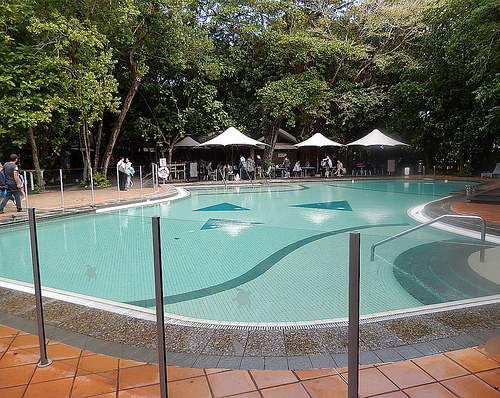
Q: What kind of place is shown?
A: It is a swimming pool.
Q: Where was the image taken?
A: It was taken at the swimming pool.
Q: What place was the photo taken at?
A: It was taken at the swimming pool.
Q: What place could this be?
A: It is a swimming pool.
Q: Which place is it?
A: It is a swimming pool.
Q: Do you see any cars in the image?
A: No, there are no cars.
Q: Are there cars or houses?
A: No, there are no cars or houses.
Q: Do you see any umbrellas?
A: Yes, there is an umbrella.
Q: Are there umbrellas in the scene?
A: Yes, there is an umbrella.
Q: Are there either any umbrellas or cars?
A: Yes, there is an umbrella.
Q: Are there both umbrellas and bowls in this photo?
A: No, there is an umbrella but no bowls.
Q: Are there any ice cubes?
A: No, there are no ice cubes.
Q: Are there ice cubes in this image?
A: No, there are no ice cubes.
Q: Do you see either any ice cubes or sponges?
A: No, there are no ice cubes or sponges.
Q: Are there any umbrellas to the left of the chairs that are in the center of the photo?
A: Yes, there is an umbrella to the left of the chairs.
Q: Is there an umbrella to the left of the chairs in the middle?
A: Yes, there is an umbrella to the left of the chairs.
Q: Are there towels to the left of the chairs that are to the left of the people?
A: No, there is an umbrella to the left of the chairs.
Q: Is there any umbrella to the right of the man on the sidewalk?
A: Yes, there is an umbrella to the right of the man.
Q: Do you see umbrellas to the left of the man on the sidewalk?
A: No, the umbrella is to the right of the man.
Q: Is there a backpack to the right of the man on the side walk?
A: No, there is an umbrella to the right of the man.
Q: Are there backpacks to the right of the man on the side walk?
A: No, there is an umbrella to the right of the man.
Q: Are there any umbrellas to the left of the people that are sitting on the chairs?
A: Yes, there is an umbrella to the left of the people.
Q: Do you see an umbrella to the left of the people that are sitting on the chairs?
A: Yes, there is an umbrella to the left of the people.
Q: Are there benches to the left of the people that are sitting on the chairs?
A: No, there is an umbrella to the left of the people.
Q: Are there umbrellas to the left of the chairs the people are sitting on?
A: Yes, there is an umbrella to the left of the chairs.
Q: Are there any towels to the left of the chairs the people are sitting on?
A: No, there is an umbrella to the left of the chairs.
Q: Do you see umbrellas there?
A: Yes, there is an umbrella.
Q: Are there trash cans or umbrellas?
A: Yes, there is an umbrella.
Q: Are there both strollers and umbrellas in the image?
A: No, there is an umbrella but no strollers.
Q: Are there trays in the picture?
A: No, there are no trays.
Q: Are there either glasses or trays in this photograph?
A: No, there are no trays or glasses.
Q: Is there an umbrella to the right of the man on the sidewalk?
A: Yes, there is an umbrella to the right of the man.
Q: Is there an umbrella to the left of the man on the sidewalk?
A: No, the umbrella is to the right of the man.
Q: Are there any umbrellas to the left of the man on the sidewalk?
A: No, the umbrella is to the right of the man.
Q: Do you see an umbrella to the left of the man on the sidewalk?
A: No, the umbrella is to the right of the man.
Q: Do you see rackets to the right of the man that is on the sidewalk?
A: No, there is an umbrella to the right of the man.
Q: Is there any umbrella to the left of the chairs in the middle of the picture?
A: Yes, there is an umbrella to the left of the chairs.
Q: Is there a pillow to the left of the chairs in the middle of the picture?
A: No, there is an umbrella to the left of the chairs.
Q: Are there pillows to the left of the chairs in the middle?
A: No, there is an umbrella to the left of the chairs.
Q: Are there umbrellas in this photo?
A: Yes, there is an umbrella.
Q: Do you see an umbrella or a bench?
A: Yes, there is an umbrella.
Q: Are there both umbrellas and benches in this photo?
A: No, there is an umbrella but no benches.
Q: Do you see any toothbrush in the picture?
A: No, there are no toothbrushes.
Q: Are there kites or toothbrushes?
A: No, there are no toothbrushes or kites.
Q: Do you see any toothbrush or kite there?
A: No, there are no toothbrushes or kites.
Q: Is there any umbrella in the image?
A: Yes, there is an umbrella.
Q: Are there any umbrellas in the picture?
A: Yes, there is an umbrella.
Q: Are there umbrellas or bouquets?
A: Yes, there is an umbrella.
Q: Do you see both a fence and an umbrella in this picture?
A: Yes, there are both an umbrella and a fence.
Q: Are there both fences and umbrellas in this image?
A: Yes, there are both an umbrella and a fence.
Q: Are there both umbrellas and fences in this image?
A: Yes, there are both an umbrella and a fence.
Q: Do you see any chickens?
A: No, there are no chickens.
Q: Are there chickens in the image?
A: No, there are no chickens.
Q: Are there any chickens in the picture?
A: No, there are no chickens.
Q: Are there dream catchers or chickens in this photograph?
A: No, there are no chickens or dream catchers.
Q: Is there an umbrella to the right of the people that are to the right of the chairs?
A: Yes, there is an umbrella to the right of the people.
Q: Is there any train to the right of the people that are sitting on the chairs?
A: No, there is an umbrella to the right of the people.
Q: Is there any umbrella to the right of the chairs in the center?
A: Yes, there is an umbrella to the right of the chairs.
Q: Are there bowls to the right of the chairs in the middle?
A: No, there is an umbrella to the right of the chairs.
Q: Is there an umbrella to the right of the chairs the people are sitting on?
A: Yes, there is an umbrella to the right of the chairs.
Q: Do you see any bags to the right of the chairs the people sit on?
A: No, there is an umbrella to the right of the chairs.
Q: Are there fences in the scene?
A: Yes, there is a fence.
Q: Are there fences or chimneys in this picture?
A: Yes, there is a fence.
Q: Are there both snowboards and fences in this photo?
A: No, there is a fence but no snowboards.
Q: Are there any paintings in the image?
A: No, there are no paintings.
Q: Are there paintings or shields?
A: No, there are no paintings or shields.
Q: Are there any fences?
A: Yes, there is a fence.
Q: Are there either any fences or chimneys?
A: Yes, there is a fence.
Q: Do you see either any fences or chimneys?
A: Yes, there is a fence.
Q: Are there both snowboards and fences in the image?
A: No, there is a fence but no snowboards.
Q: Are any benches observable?
A: No, there are no benches.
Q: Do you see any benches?
A: No, there are no benches.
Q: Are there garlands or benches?
A: No, there are no benches or garlands.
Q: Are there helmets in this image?
A: No, there are no helmets.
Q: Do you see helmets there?
A: No, there are no helmets.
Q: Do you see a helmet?
A: No, there are no helmets.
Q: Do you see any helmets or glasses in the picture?
A: No, there are no helmets or glasses.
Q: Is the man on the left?
A: Yes, the man is on the left of the image.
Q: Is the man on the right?
A: No, the man is on the left of the image.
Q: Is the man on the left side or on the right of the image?
A: The man is on the left of the image.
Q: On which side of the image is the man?
A: The man is on the left of the image.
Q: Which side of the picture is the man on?
A: The man is on the left of the image.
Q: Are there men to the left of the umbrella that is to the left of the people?
A: Yes, there is a man to the left of the umbrella.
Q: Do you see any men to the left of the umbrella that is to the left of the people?
A: Yes, there is a man to the left of the umbrella.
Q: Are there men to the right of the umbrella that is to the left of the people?
A: No, the man is to the left of the umbrella.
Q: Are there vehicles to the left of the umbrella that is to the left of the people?
A: No, there is a man to the left of the umbrella.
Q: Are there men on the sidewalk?
A: Yes, there is a man on the sidewalk.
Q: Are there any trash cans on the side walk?
A: No, there is a man on the side walk.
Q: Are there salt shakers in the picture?
A: No, there are no salt shakers.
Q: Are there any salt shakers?
A: No, there are no salt shakers.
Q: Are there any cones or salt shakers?
A: No, there are no salt shakers or cones.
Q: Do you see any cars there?
A: No, there are no cars.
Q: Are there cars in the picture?
A: No, there are no cars.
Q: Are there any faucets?
A: No, there are no faucets.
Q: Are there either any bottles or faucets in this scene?
A: No, there are no faucets or bottles.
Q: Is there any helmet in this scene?
A: No, there are no helmets.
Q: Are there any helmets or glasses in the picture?
A: No, there are no helmets or glasses.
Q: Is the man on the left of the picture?
A: Yes, the man is on the left of the image.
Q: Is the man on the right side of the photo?
A: No, the man is on the left of the image.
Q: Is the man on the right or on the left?
A: The man is on the left of the image.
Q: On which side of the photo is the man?
A: The man is on the left of the image.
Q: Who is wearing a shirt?
A: The man is wearing a shirt.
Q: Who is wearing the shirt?
A: The man is wearing a shirt.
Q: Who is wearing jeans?
A: The man is wearing jeans.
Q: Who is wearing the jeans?
A: The man is wearing jeans.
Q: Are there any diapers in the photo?
A: No, there are no diapers.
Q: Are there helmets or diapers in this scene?
A: No, there are no diapers or helmets.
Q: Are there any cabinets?
A: No, there are no cabinets.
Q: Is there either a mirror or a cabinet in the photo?
A: No, there are no cabinets or mirrors.